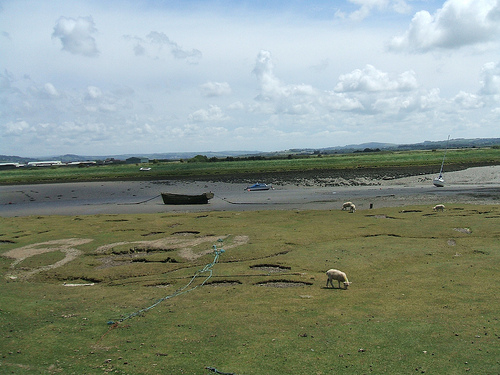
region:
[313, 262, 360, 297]
a sheep on the grass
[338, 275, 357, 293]
the head of a sheep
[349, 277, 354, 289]
the ear of a sheep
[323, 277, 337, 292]
the hind legs of a sheep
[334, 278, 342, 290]
a front leg of a sheep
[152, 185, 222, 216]
a boat on the shore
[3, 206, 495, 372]
a green grassy field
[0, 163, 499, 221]
a sandy beach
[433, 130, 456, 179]
the mast of a boat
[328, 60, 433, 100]
a white cloud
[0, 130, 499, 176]
Mountains are in the background.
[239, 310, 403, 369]
The ground is green.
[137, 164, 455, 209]
Boats are on the ground.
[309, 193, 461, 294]
Sheep are grazing.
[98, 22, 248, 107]
Clouds are in the sky.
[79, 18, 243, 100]
The clouds are white and gray.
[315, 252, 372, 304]
The sheep is white.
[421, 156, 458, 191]
The boat is white.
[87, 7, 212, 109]
The sky is bright.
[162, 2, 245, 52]
The sky is blue and white.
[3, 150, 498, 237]
the tide is out for the boats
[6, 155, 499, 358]
low lying green grass is near the tidal basin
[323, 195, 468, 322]
sheep are grazing in the low lying areas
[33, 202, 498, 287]
sink holes dot the area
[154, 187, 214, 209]
a wooden boat is sitting on the sand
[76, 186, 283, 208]
the bow and stern are anchored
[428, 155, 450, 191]
a sailboat is on its side in the sand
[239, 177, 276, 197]
a motorboat is sitting in the sand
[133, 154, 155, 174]
a structure is sitting in the grass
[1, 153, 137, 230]
buildings are in the distance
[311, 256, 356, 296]
sheep standing on the grass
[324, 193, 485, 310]
four sheep on the grass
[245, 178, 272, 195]
blue and white speedboat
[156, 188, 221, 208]
brown boat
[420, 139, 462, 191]
tall white boat leaning to the side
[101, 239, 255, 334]
green wires running alont the grass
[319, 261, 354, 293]
sheep grazing on the grass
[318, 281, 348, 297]
shadow from the sheep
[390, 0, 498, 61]
big puffy cloud in the sky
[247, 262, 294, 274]
shallow hole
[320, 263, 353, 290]
white sheep grazing on the grass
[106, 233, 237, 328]
green wires running along the grass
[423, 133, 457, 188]
small white boat leaning to the side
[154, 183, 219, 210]
small brown boat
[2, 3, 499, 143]
light sky filled with puffy white clouds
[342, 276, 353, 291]
face on the grass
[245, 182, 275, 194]
blue and white speed boat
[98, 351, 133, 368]
rocks on the grass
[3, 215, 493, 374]
field of green grass